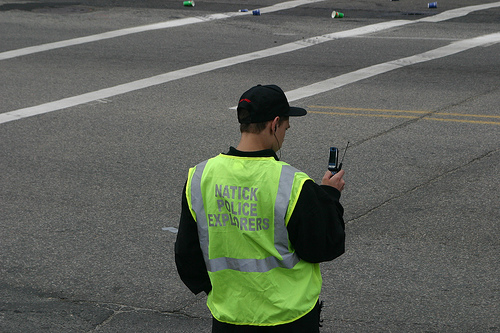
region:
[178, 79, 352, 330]
back of standing man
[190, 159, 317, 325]
yellow vest with gray words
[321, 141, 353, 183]
open flip phone in hand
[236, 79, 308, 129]
black cap on head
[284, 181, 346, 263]
arm in black sleeve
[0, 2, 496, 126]
three white lines on road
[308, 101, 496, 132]
double yellow lines on street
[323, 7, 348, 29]
cup laying on street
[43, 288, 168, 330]
cracks in asphalt surface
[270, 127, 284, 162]
black wire in ear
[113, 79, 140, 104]
white piece of line on the ground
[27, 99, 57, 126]
white piece of line on the ground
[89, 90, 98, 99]
white piece of line on the ground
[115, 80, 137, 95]
white piece of line on the ground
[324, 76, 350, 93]
white piece of line on the ground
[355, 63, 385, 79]
white piece of line on the ground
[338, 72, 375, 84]
white piece of line on the ground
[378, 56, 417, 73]
white piece of line on the ground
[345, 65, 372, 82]
white piece of line on the ground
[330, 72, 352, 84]
white piece of line on the ground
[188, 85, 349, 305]
The police is holding a cellphone.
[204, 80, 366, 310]
The man is standing in the street.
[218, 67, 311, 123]
The man is wearing a black cap.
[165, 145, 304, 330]
The man has on a yellow vest.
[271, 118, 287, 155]
The man has earplugs in his ear.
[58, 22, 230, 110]
The street has white lines.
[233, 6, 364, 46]
Trash on the ground.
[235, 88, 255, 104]
A red logo on the back of the cap.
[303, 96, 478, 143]
Two yellow lines in the street.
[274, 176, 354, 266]
The man is wearing a black shirt.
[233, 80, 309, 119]
black baseball cap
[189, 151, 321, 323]
bright green reflective vest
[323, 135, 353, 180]
a cell phone with an antenna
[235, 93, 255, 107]
red logo on a hat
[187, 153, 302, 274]
reflective strips on a jacket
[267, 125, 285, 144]
headphones in a man's ears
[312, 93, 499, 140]
yellow stripes on the road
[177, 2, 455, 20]
paper cups on the ground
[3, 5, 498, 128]
white lines on the pavement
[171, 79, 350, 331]
a man standing in the road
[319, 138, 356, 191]
Blue and black cell phone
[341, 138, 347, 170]
Black antena on cell phone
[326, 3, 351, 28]
Green cup on pavement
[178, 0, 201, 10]
Green cup on pavement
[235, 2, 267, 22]
Blue cups in pavement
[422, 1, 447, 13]
Blue cup on pavement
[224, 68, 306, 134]
Black hat with red lettering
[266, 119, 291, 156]
Black ear phones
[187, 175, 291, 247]
Yellow jacket wiht grey lettering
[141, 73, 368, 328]
Man holding a blue cell phone